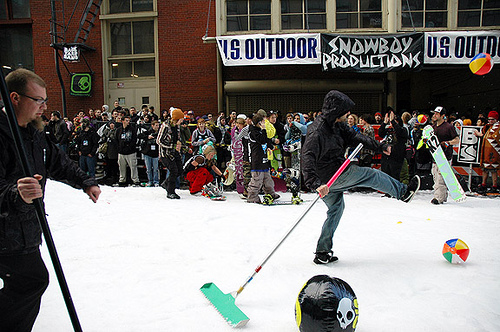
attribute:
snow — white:
[6, 172, 484, 314]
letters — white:
[323, 35, 421, 69]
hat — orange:
[168, 104, 183, 120]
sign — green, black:
[68, 70, 93, 94]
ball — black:
[294, 270, 363, 330]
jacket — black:
[298, 84, 386, 189]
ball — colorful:
[467, 47, 495, 75]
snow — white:
[31, 180, 497, 330]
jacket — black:
[298, 90, 377, 192]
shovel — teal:
[198, 280, 248, 329]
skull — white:
[335, 296, 355, 330]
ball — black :
[294, 275, 360, 330]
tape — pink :
[327, 158, 350, 188]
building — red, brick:
[26, 0, 498, 122]